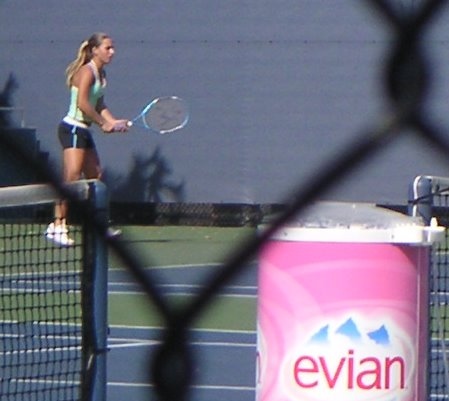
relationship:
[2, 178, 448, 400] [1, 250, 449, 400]
nets seperate courts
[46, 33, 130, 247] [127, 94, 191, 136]
player holding racket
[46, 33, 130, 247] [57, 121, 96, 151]
person wearing shorts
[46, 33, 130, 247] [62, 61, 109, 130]
person wearing green shirt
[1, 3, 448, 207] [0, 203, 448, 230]
wall has black bottom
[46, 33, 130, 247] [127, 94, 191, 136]
person holding racket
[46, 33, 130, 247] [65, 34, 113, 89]
person with long hair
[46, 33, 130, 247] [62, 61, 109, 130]
person wearing blue top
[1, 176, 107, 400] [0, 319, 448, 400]
net at court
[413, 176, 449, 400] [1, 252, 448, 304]
net at court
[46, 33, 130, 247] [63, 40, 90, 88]
person has ponytail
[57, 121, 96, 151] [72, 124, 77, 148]
shorts have stripe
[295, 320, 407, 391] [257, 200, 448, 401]
logo on trash can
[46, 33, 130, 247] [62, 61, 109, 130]
person wears green shirt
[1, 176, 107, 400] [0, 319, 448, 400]
net on court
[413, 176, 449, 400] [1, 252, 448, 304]
net on court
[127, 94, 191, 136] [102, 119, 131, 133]
racket in hands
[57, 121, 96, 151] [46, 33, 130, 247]
shorts on person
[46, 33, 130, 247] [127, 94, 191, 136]
person holds racket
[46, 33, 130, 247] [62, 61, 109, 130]
person wears shirt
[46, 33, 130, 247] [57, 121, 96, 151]
person wears shorts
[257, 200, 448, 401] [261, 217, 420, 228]
container for water bottles